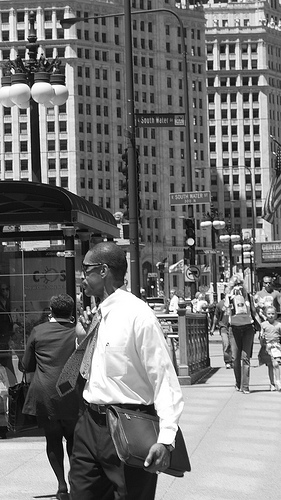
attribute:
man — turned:
[50, 244, 193, 498]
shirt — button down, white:
[68, 287, 188, 448]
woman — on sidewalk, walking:
[220, 274, 264, 397]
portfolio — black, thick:
[103, 403, 194, 480]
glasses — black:
[76, 261, 104, 273]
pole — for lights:
[24, 13, 49, 196]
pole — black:
[118, 5, 151, 309]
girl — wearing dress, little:
[260, 305, 281, 392]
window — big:
[0, 250, 77, 384]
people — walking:
[213, 269, 280, 392]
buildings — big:
[2, 1, 280, 316]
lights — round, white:
[2, 59, 74, 110]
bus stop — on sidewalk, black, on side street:
[1, 177, 124, 447]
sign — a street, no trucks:
[181, 267, 203, 288]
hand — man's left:
[140, 444, 174, 481]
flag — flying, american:
[258, 156, 277, 229]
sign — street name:
[134, 110, 193, 132]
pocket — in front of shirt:
[105, 327, 124, 357]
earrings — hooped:
[68, 313, 79, 325]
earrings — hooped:
[46, 312, 54, 323]